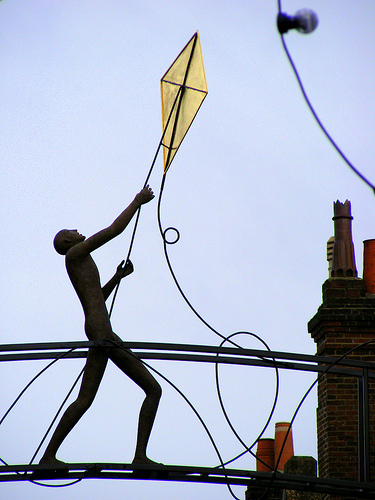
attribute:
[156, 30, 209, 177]
kite — yellow, white, statue, metal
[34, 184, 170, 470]
statue — of a ma, metal, a man, bald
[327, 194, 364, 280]
chimneys — in background, dark brown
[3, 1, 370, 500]
sky — blue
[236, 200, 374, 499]
building — brick, tall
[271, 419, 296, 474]
smoke towers — orange